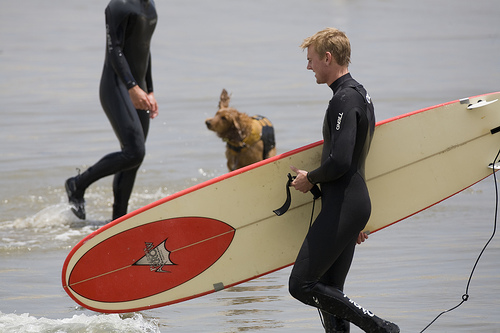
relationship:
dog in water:
[206, 88, 277, 172] [0, 1, 498, 332]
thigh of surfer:
[291, 203, 360, 282] [289, 25, 401, 332]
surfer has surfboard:
[289, 25, 401, 332] [63, 91, 500, 313]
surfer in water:
[64, 1, 158, 221] [0, 1, 498, 332]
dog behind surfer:
[206, 88, 277, 172] [289, 25, 401, 332]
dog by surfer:
[206, 88, 277, 172] [64, 1, 158, 221]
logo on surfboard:
[132, 237, 179, 273] [63, 91, 500, 313]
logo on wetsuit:
[335, 110, 344, 130] [288, 72, 400, 331]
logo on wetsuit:
[105, 21, 114, 53] [74, 1, 158, 219]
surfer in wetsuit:
[64, 1, 158, 221] [74, 1, 158, 219]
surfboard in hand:
[63, 91, 500, 313] [354, 231, 368, 244]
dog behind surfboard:
[206, 88, 277, 172] [63, 91, 500, 313]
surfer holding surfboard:
[289, 25, 401, 332] [63, 91, 500, 313]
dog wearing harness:
[206, 88, 277, 172] [227, 113, 276, 160]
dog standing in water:
[206, 88, 277, 172] [0, 1, 498, 332]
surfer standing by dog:
[289, 25, 401, 332] [206, 88, 277, 172]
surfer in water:
[289, 25, 401, 332] [0, 1, 498, 332]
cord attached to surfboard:
[310, 150, 500, 332] [63, 91, 500, 313]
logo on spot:
[132, 237, 179, 273] [69, 216, 235, 303]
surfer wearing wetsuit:
[289, 25, 401, 332] [288, 72, 400, 331]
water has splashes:
[0, 1, 498, 332] [1, 169, 213, 332]